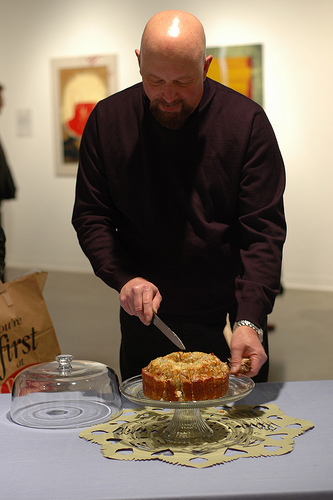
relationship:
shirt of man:
[71, 80, 290, 322] [78, 8, 286, 384]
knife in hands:
[150, 314, 187, 351] [118, 279, 264, 376]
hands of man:
[118, 279, 264, 376] [78, 8, 286, 384]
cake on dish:
[144, 347, 226, 398] [119, 375, 251, 447]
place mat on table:
[82, 397, 315, 474] [1, 376, 327, 499]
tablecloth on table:
[4, 385, 333, 499] [1, 376, 327, 499]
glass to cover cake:
[14, 353, 115, 427] [144, 347, 226, 398]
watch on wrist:
[237, 316, 271, 342] [227, 300, 274, 340]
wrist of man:
[227, 300, 274, 340] [78, 8, 286, 384]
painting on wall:
[45, 58, 122, 174] [2, 1, 331, 291]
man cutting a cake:
[78, 8, 286, 384] [144, 347, 226, 398]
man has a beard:
[78, 8, 286, 384] [153, 94, 188, 127]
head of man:
[138, 13, 206, 114] [78, 8, 286, 384]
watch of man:
[237, 316, 271, 342] [78, 8, 286, 384]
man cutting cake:
[78, 8, 286, 384] [144, 347, 226, 398]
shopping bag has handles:
[2, 276, 65, 396] [1, 274, 15, 309]